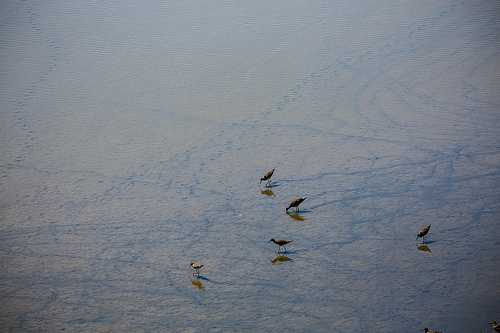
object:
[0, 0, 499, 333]
water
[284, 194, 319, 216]
bird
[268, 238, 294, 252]
bird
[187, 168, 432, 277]
birds flock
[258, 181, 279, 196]
shadow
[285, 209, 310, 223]
shadow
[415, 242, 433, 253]
shadow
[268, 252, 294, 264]
shadow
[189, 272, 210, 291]
shadow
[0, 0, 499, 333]
ice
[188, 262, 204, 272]
bird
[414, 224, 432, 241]
bird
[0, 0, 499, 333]
iced surface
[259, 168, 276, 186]
bird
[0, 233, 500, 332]
sand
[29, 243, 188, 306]
lines